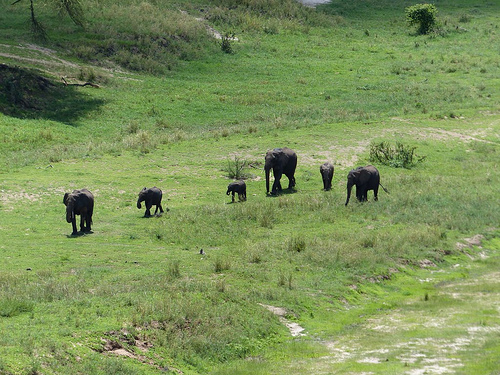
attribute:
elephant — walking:
[315, 157, 336, 194]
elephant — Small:
[320, 160, 337, 189]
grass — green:
[1, 1, 499, 373]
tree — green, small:
[402, 5, 439, 40]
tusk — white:
[68, 207, 75, 221]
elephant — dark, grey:
[247, 119, 304, 204]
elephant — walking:
[340, 167, 385, 203]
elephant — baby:
[217, 175, 252, 211]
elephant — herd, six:
[346, 164, 387, 201]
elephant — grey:
[58, 190, 93, 240]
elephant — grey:
[136, 183, 166, 218]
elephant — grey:
[263, 142, 298, 197]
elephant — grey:
[346, 154, 387, 206]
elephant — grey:
[316, 152, 334, 199]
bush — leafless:
[223, 150, 251, 182]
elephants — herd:
[51, 146, 395, 237]